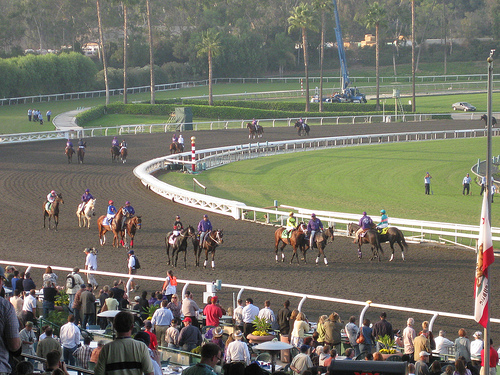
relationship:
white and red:
[481, 233, 491, 240] [485, 252, 495, 262]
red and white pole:
[485, 252, 495, 262] [489, 78, 492, 150]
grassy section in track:
[286, 161, 335, 189] [5, 162, 133, 189]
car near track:
[454, 101, 474, 113] [5, 162, 133, 189]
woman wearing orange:
[164, 268, 177, 290] [172, 279, 176, 284]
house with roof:
[83, 41, 98, 55] [87, 43, 98, 47]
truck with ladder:
[328, 88, 365, 104] [334, 22, 345, 61]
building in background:
[83, 41, 98, 55] [62, 17, 129, 60]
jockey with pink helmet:
[48, 188, 57, 205] [50, 190, 56, 194]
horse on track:
[274, 225, 310, 260] [5, 162, 133, 189]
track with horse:
[5, 162, 133, 189] [274, 225, 310, 260]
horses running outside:
[40, 188, 143, 248] [6, 74, 498, 263]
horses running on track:
[40, 188, 143, 248] [5, 162, 133, 189]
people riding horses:
[287, 211, 322, 224] [40, 188, 143, 248]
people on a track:
[287, 211, 322, 224] [5, 162, 133, 189]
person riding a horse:
[198, 214, 212, 234] [274, 225, 310, 260]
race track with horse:
[233, 227, 257, 272] [274, 225, 310, 260]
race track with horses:
[233, 227, 257, 272] [40, 188, 143, 248]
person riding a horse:
[107, 199, 117, 214] [274, 225, 310, 260]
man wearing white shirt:
[243, 298, 259, 325] [245, 307, 257, 322]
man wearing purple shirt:
[243, 305, 261, 320] [200, 220, 211, 232]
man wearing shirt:
[243, 305, 261, 320] [245, 307, 257, 322]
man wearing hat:
[243, 305, 261, 320] [83, 246, 91, 256]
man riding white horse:
[243, 305, 261, 320] [76, 199, 97, 227]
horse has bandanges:
[274, 225, 310, 260] [273, 252, 286, 262]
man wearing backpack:
[126, 248, 141, 276] [133, 257, 141, 270]